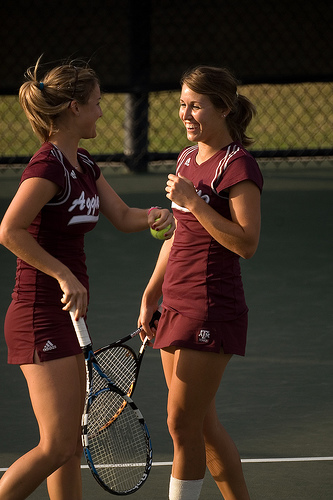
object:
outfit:
[3, 142, 101, 366]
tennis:
[5, 2, 332, 498]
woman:
[0, 59, 176, 499]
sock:
[169, 475, 205, 499]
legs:
[165, 349, 234, 497]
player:
[138, 64, 264, 497]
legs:
[2, 348, 86, 498]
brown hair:
[182, 66, 258, 147]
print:
[68, 189, 99, 226]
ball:
[149, 216, 174, 240]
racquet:
[86, 309, 161, 435]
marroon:
[151, 143, 264, 358]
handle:
[69, 300, 92, 349]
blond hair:
[18, 53, 100, 143]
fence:
[1, 0, 332, 171]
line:
[1, 456, 332, 473]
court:
[1, 166, 332, 500]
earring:
[220, 114, 224, 119]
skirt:
[151, 307, 248, 358]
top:
[162, 144, 264, 322]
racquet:
[69, 312, 153, 494]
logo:
[43, 340, 57, 353]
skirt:
[4, 312, 84, 365]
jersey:
[11, 140, 101, 303]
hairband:
[38, 80, 44, 90]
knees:
[50, 426, 84, 470]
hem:
[7, 351, 85, 367]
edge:
[81, 399, 95, 479]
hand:
[137, 297, 159, 345]